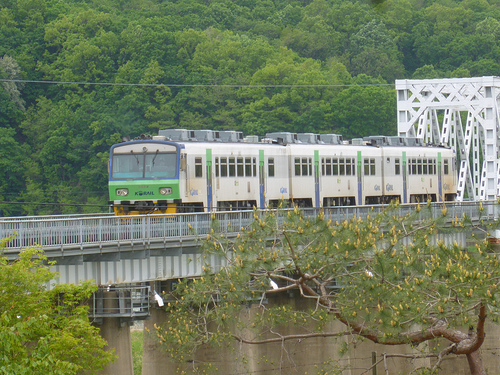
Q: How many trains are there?
A: One.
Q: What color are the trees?
A: Green.